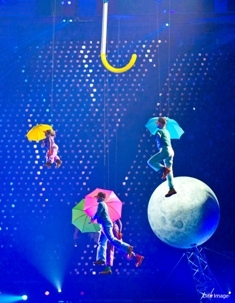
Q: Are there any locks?
A: No, there are no locks.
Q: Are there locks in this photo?
A: No, there are no locks.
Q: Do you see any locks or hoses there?
A: No, there are no locks or hoses.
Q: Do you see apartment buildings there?
A: No, there are no apartment buildings.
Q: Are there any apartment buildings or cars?
A: No, there are no apartment buildings or cars.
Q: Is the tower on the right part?
A: Yes, the tower is on the right of the image.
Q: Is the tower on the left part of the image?
A: No, the tower is on the right of the image.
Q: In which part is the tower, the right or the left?
A: The tower is on the right of the image.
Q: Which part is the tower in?
A: The tower is on the right of the image.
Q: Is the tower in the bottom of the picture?
A: Yes, the tower is in the bottom of the image.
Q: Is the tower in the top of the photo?
A: No, the tower is in the bottom of the image.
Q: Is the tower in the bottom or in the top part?
A: The tower is in the bottom of the image.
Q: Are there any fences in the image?
A: No, there are no fences.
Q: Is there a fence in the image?
A: No, there are no fences.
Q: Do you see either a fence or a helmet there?
A: No, there are no fences or helmets.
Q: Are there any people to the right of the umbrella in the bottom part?
A: Yes, there is a person to the right of the umbrella.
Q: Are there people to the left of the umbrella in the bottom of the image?
A: No, the person is to the right of the umbrella.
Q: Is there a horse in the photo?
A: No, there are no horses.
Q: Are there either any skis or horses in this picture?
A: No, there are no horses or skis.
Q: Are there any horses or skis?
A: No, there are no horses or skis.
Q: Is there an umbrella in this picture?
A: Yes, there is an umbrella.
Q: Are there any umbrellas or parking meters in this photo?
A: Yes, there is an umbrella.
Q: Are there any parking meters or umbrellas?
A: Yes, there is an umbrella.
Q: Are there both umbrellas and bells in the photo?
A: No, there is an umbrella but no bells.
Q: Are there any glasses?
A: No, there are no glasses.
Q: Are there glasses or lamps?
A: No, there are no glasses or lamps.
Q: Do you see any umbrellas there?
A: Yes, there is an umbrella.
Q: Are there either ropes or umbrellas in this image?
A: Yes, there is an umbrella.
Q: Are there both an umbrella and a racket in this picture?
A: No, there is an umbrella but no rackets.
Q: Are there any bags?
A: No, there are no bags.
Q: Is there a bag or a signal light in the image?
A: No, there are no bags or traffic lights.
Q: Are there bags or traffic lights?
A: No, there are no bags or traffic lights.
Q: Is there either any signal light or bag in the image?
A: No, there are no bags or traffic lights.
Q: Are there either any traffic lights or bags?
A: No, there are no bags or traffic lights.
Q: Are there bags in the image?
A: No, there are no bags.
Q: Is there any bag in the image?
A: No, there are no bags.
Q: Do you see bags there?
A: No, there are no bags.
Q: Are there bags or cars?
A: No, there are no bags or cars.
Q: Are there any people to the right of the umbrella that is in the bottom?
A: Yes, there are people to the right of the umbrella.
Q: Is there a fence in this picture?
A: No, there are no fences.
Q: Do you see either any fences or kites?
A: No, there are no fences or kites.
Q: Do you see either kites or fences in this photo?
A: No, there are no fences or kites.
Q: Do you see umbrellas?
A: Yes, there is an umbrella.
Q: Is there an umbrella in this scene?
A: Yes, there is an umbrella.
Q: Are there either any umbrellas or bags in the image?
A: Yes, there is an umbrella.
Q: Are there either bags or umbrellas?
A: Yes, there is an umbrella.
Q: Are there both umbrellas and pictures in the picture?
A: No, there is an umbrella but no pictures.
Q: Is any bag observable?
A: No, there are no bags.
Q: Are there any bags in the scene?
A: No, there are no bags.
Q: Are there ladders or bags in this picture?
A: No, there are no bags or ladders.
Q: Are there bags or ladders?
A: No, there are no bags or ladders.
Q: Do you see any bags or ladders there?
A: No, there are no bags or ladders.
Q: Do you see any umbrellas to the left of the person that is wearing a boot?
A: Yes, there is an umbrella to the left of the person.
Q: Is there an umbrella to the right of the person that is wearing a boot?
A: No, the umbrella is to the left of the person.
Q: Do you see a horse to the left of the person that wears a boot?
A: No, there is an umbrella to the left of the person.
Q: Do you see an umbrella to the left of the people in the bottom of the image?
A: Yes, there is an umbrella to the left of the people.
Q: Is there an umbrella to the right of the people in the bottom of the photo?
A: No, the umbrella is to the left of the people.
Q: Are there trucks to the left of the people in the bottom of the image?
A: No, there is an umbrella to the left of the people.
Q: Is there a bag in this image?
A: No, there are no bags.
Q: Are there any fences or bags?
A: No, there are no bags or fences.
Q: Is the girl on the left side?
A: Yes, the girl is on the left of the image.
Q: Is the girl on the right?
A: No, the girl is on the left of the image.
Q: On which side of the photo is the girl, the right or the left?
A: The girl is on the left of the image.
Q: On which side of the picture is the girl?
A: The girl is on the left of the image.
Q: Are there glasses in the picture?
A: No, there are no glasses.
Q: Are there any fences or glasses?
A: No, there are no glasses or fences.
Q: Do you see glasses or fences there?
A: No, there are no glasses or fences.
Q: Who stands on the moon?
A: The man stands on the moon.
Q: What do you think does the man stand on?
A: The man stands on the moon.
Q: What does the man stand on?
A: The man stands on the moon.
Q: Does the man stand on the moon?
A: Yes, the man stands on the moon.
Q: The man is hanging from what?
A: The man is hanging from the wires.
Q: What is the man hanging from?
A: The man is hanging from the wires.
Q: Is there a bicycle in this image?
A: No, there are no bicycles.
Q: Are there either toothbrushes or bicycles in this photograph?
A: No, there are no bicycles or toothbrushes.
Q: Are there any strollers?
A: No, there are no strollers.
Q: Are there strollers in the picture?
A: No, there are no strollers.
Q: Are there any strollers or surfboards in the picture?
A: No, there are no strollers or surfboards.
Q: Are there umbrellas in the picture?
A: Yes, there is an umbrella.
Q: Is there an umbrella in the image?
A: Yes, there is an umbrella.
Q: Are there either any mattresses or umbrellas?
A: Yes, there is an umbrella.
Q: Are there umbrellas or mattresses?
A: Yes, there is an umbrella.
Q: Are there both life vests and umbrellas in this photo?
A: No, there is an umbrella but no life jackets.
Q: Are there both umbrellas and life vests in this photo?
A: No, there is an umbrella but no life jackets.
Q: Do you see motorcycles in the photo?
A: No, there are no motorcycles.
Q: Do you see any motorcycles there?
A: No, there are no motorcycles.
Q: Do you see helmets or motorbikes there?
A: No, there are no motorbikes or helmets.